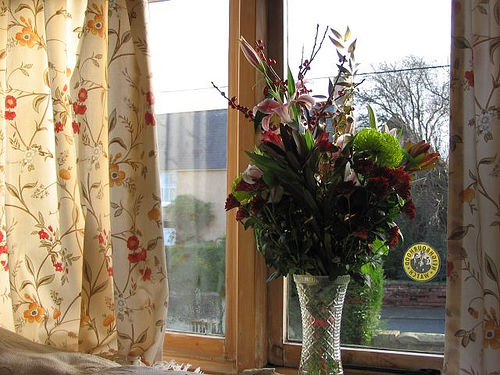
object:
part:
[284, 182, 298, 203]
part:
[322, 316, 329, 330]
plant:
[210, 22, 440, 374]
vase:
[293, 274, 352, 374]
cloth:
[1, 324, 208, 374]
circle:
[402, 243, 440, 282]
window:
[144, 1, 229, 338]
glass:
[284, 0, 450, 355]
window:
[239, 0, 452, 374]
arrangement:
[210, 22, 441, 285]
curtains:
[0, 0, 168, 366]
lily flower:
[252, 79, 313, 132]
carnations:
[224, 192, 240, 209]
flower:
[352, 127, 403, 166]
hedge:
[161, 191, 227, 315]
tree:
[356, 51, 449, 282]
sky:
[149, 1, 451, 164]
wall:
[235, 0, 258, 375]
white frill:
[135, 358, 207, 374]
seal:
[141, 0, 240, 364]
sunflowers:
[16, 25, 45, 49]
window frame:
[256, 0, 464, 375]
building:
[158, 169, 228, 249]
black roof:
[153, 108, 227, 170]